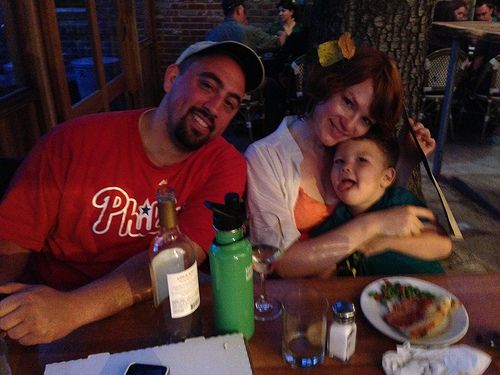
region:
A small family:
[22, 10, 450, 370]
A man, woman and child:
[11, 37, 483, 321]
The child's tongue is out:
[341, 177, 352, 187]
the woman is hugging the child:
[267, 74, 474, 302]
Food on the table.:
[352, 244, 466, 374]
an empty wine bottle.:
[125, 187, 203, 327]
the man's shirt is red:
[67, 143, 94, 173]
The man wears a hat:
[182, 48, 239, 62]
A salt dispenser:
[331, 300, 352, 365]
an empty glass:
[281, 281, 323, 362]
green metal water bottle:
[203, 186, 260, 346]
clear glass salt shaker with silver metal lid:
[327, 297, 360, 364]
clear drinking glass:
[278, 285, 332, 370]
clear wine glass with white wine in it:
[241, 206, 288, 323]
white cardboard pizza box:
[41, 330, 261, 373]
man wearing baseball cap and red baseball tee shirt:
[1, 37, 269, 350]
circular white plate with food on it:
[354, 273, 471, 348]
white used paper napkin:
[381, 339, 494, 373]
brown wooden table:
[1, 270, 498, 373]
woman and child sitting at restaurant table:
[226, 31, 466, 282]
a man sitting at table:
[4, 39, 263, 343]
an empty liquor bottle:
[142, 182, 204, 341]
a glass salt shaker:
[324, 298, 359, 365]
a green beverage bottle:
[204, 189, 259, 339]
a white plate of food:
[358, 275, 470, 347]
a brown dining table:
[1, 278, 496, 373]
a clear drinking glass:
[277, 285, 328, 368]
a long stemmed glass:
[246, 210, 284, 325]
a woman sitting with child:
[244, 47, 453, 275]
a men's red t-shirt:
[4, 108, 248, 280]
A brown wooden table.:
[0, 262, 497, 373]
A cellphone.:
[122, 360, 173, 373]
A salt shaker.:
[329, 299, 358, 363]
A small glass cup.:
[280, 287, 328, 364]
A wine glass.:
[242, 207, 292, 323]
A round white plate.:
[362, 265, 469, 351]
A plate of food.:
[362, 265, 470, 346]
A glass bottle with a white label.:
[151, 185, 205, 337]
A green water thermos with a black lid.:
[204, 188, 256, 343]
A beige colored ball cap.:
[168, 39, 265, 91]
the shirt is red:
[59, 113, 314, 321]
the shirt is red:
[66, 97, 198, 263]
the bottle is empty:
[145, 176, 215, 337]